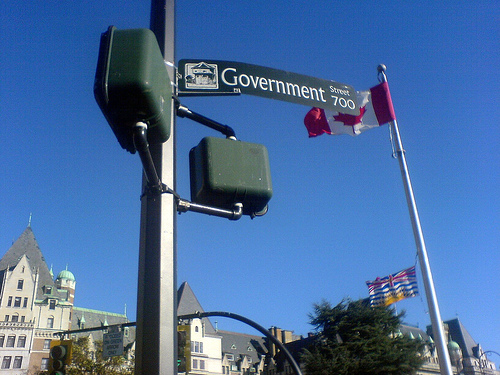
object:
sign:
[183, 61, 357, 111]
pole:
[133, 0, 176, 375]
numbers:
[331, 95, 357, 110]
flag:
[365, 265, 419, 310]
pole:
[376, 64, 451, 375]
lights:
[43, 344, 64, 371]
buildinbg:
[0, 226, 57, 371]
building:
[54, 262, 76, 304]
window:
[18, 280, 24, 290]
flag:
[304, 81, 397, 138]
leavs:
[331, 315, 354, 345]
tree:
[298, 294, 433, 374]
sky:
[10, 36, 43, 59]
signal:
[91, 24, 172, 155]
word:
[221, 67, 328, 103]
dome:
[448, 335, 461, 350]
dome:
[57, 270, 76, 281]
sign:
[99, 333, 122, 358]